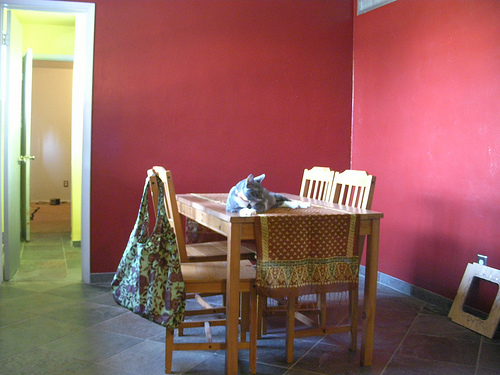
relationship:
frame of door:
[1, 2, 96, 286] [5, 10, 22, 280]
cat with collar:
[222, 163, 313, 222] [236, 189, 249, 205]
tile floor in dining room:
[4, 281, 414, 373] [0, 2, 496, 373]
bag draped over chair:
[108, 166, 186, 327] [140, 162, 260, 374]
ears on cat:
[241, 169, 266, 185] [222, 168, 315, 220]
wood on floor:
[464, 267, 497, 336] [80, 292, 497, 374]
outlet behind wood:
[477, 252, 487, 264] [445, 262, 498, 338]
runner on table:
[254, 214, 374, 319] [166, 190, 381, 369]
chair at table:
[140, 162, 260, 374] [166, 190, 381, 369]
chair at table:
[145, 167, 255, 371] [166, 190, 381, 369]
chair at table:
[241, 164, 334, 328] [166, 190, 381, 369]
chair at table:
[260, 171, 377, 368] [166, 190, 381, 369]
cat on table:
[225, 174, 311, 217] [166, 190, 381, 369]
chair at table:
[145, 167, 255, 371] [166, 187, 408, 364]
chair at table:
[140, 162, 260, 374] [166, 187, 408, 364]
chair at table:
[260, 166, 377, 365] [166, 187, 408, 364]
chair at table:
[241, 164, 334, 328] [166, 187, 408, 364]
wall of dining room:
[94, 1, 351, 281] [0, 2, 496, 373]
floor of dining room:
[0, 226, 497, 371] [0, 2, 496, 373]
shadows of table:
[192, 199, 496, 373] [166, 190, 381, 369]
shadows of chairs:
[192, 199, 496, 373] [143, 162, 376, 372]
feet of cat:
[234, 195, 315, 219] [222, 168, 315, 220]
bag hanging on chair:
[108, 166, 186, 327] [140, 162, 260, 374]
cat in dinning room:
[225, 174, 311, 217] [5, 1, 497, 370]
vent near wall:
[357, 1, 393, 13] [351, 0, 498, 330]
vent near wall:
[357, 1, 393, 13] [56, 0, 356, 283]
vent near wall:
[357, 1, 393, 13] [9, 15, 79, 243]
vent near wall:
[357, 1, 393, 13] [31, 67, 68, 204]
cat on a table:
[225, 174, 311, 217] [151, 164, 395, 343]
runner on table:
[254, 214, 374, 319] [175, 177, 385, 363]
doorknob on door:
[28, 152, 34, 160] [24, 47, 34, 237]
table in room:
[166, 190, 381, 369] [3, 4, 498, 372]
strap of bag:
[140, 165, 175, 230] [108, 166, 186, 327]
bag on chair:
[108, 166, 186, 327] [140, 162, 260, 374]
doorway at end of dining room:
[31, 59, 73, 241] [0, 2, 496, 373]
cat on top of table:
[225, 174, 311, 217] [166, 190, 381, 369]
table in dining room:
[166, 190, 381, 369] [0, 2, 496, 373]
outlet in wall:
[477, 252, 487, 264] [351, 0, 498, 330]